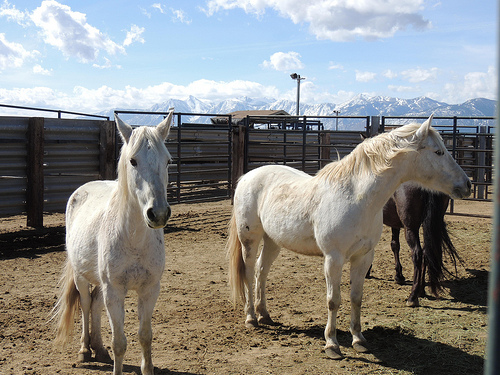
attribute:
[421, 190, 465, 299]
horse tail — dark 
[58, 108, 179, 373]
horse — white , still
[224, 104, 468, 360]
horse — still, white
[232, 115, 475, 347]
horse — white 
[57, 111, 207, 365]
horse — white